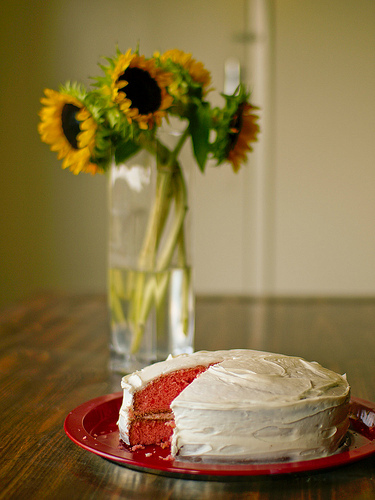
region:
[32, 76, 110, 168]
a small yellow sunflower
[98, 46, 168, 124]
a small yellow sunflower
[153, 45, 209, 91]
a small yellow sunflower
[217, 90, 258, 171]
a small yellow sunflower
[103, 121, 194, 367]
a clear glass vase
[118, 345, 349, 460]
a red velvet cake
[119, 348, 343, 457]
small cake with white icing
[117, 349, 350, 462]
cake with piece missing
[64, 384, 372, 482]
a dark red plate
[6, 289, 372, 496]
a dark brown table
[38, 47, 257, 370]
sunflowers in a vase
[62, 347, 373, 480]
white frosted cake on a plate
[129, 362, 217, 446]
section of a cake that is missing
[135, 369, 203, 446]
red interior of a cake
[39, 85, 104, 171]
the head of a sunflower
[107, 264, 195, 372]
water in a vase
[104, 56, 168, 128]
head of a sunflower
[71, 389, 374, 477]
a red plate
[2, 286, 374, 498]
large wooden table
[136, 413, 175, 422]
frosting inside of a cake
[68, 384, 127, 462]
red pie pan on table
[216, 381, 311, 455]
cake with creamy white icing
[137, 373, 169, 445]
pink cake with icing in between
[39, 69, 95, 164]
sunflower on left of photo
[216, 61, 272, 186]
sunflower on right of photo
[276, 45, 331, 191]
white wall behind table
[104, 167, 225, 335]
glass vase filled with flowers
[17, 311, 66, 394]
brown wooden table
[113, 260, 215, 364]
water in bottom of vase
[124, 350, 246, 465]
cake with a slice taken out of it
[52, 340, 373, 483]
a carrot cake on a red dish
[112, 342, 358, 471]
carrot cake is covered with white frosting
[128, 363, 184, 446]
cake is color orange inside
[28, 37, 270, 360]
four sunflowers in a vase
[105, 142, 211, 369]
stem of sunflowers in a vase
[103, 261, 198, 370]
stem of sunflowers in water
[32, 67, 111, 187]
petals of sunflower is yellow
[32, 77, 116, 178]
green leaves under petals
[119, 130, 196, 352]
long stems of sunflowers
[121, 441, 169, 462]
crumbs of cake on red dish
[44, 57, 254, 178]
Five sunflowers bunched together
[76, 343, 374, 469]
Cake in on a red plate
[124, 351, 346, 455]
The cake has white frosting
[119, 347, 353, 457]
The cake has a piece cut out of it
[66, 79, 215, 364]
Cut flowers in water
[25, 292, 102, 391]
The table is brown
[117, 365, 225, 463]
The cake has two layers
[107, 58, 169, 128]
The sunflower has green leaves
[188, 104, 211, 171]
The leaf of a sunflower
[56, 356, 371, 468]
The plate is round